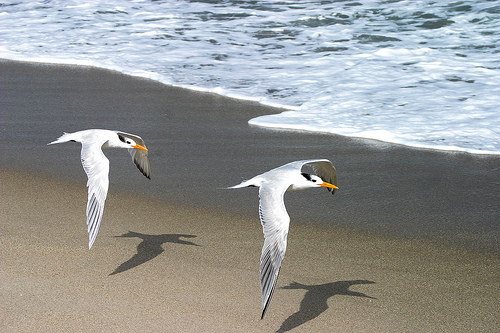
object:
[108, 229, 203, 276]
shadow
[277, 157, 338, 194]
wing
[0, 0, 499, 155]
sea water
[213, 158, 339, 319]
bird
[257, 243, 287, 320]
gray feathers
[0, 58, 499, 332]
sand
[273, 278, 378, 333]
shadow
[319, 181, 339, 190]
beak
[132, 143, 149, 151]
beak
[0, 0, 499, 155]
waves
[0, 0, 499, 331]
beach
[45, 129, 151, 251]
bird